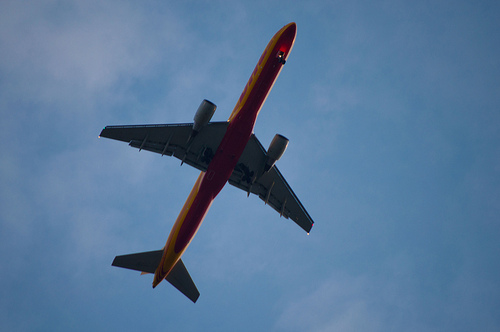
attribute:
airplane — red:
[42, 12, 354, 322]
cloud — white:
[0, 1, 195, 110]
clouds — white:
[2, 3, 226, 328]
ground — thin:
[376, 115, 432, 185]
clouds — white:
[0, 3, 425, 329]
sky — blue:
[0, 0, 498, 329]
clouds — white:
[213, 236, 494, 331]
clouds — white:
[19, 7, 192, 124]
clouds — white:
[37, 8, 349, 280]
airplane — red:
[87, 17, 354, 326]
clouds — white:
[322, 185, 495, 321]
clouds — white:
[207, 235, 314, 321]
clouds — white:
[3, 162, 107, 327]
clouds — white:
[5, 5, 92, 182]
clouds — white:
[95, 5, 230, 98]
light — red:
[255, 18, 284, 67]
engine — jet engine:
[241, 127, 328, 184]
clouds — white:
[303, 77, 359, 113]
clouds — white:
[41, 20, 146, 88]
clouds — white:
[1, 185, 37, 232]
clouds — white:
[63, 205, 130, 255]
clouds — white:
[266, 280, 383, 330]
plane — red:
[38, 13, 340, 316]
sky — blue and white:
[348, 36, 465, 168]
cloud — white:
[12, 10, 168, 269]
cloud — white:
[268, 287, 382, 328]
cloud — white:
[321, 17, 431, 119]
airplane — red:
[93, 14, 326, 313]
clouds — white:
[291, 298, 376, 328]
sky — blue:
[41, 225, 113, 329]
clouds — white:
[33, 12, 201, 90]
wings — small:
[112, 247, 167, 275]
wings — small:
[162, 258, 201, 302]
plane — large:
[98, 20, 315, 302]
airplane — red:
[57, 10, 371, 328]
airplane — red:
[99, 22, 314, 301]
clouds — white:
[0, 3, 190, 118]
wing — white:
[82, 121, 232, 176]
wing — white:
[227, 129, 315, 238]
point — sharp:
[289, 19, 298, 29]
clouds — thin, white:
[0, 1, 495, 325]